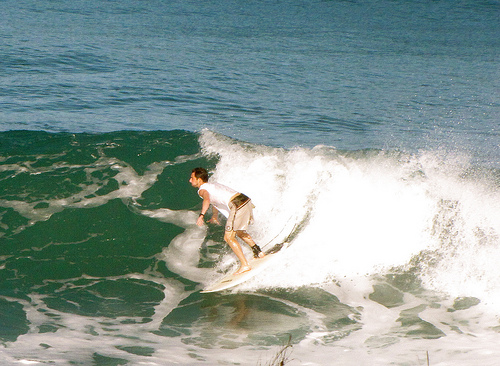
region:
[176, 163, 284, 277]
man on a surfboard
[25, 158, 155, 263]
green ocean water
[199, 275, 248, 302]
surfboard in the ocean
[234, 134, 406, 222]
ocean wave breaking behind the surfer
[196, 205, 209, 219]
watch on the wrist of the surfer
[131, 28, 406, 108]
vast ocean water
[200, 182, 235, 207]
surfer wearing a white shirt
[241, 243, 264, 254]
ankle wrap connected to the surfboard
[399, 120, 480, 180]
water spray from the breaking wave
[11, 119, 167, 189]
wave toppling over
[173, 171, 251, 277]
man is surfing on water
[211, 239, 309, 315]
man has white board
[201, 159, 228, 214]
man has white shirt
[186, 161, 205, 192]
man has brown hair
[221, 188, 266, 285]
man has grey pants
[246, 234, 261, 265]
black cable around ankle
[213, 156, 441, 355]
white wave is crashing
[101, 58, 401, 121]
blue and calm water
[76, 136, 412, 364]
waves crashing near man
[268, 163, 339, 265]
white wake behind board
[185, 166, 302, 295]
Surfer on his surfing board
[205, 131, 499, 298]
Sea wave crest near the surfer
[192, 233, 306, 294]
White surf board near the sea waves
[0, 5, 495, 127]
Blue sea in the back ground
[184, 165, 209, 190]
surfer head facing the waves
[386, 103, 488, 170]
Sea water splashes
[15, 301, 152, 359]
Sea water bubbles near the surfer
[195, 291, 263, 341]
reflection of surfer in the sea water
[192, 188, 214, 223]
Surfer's arm balancing on board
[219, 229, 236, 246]
Surfer's knees bent to help balance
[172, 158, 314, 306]
The man is surfing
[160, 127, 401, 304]
The man is surfing on a wave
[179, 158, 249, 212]
The man is wearing a white shirt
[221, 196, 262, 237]
The man is wearing white shorts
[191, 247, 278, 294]
The man has a white surfboard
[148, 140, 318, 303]
The surfer surfs on the surfboard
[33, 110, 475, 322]
Waves roll behind the surfer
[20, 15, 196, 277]
The water is a blue green color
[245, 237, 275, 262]
The man has a rope on his ankle to the surfboard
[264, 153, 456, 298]
Foam is on the top of the water